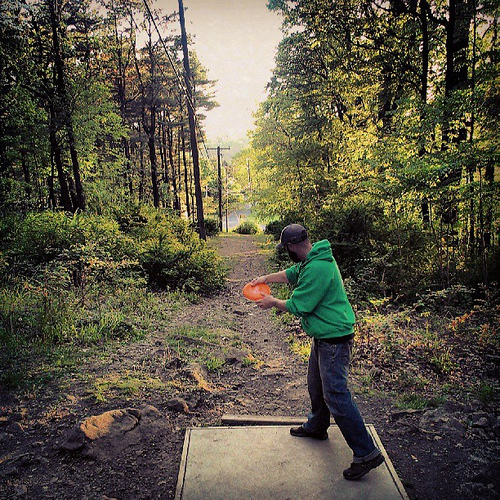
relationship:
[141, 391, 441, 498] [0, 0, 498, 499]
platform in woods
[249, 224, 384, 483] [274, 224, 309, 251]
man wears cap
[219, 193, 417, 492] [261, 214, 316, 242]
man wearing cap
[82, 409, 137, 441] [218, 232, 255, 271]
footprints in road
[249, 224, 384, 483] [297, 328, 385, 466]
man wearing blue jeans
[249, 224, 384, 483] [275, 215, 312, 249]
man wearing a cap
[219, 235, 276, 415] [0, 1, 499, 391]
path in forest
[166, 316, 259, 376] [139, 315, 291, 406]
green grass growing on dirt path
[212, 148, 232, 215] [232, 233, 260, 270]
pole beside path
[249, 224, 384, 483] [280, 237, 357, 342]
man wearing a green jacket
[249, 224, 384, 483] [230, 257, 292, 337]
man holding frisbee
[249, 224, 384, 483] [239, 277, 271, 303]
man throwing a frisbee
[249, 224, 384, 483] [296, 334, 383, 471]
man wearing blue jeans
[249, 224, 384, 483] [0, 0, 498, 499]
man standing in woods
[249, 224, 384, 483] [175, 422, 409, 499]
man standing on platform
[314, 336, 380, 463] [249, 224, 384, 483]
leg on man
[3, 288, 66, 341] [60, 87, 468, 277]
green vegetation in field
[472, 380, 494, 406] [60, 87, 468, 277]
green vegetation in field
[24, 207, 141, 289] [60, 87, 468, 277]
vegetation in field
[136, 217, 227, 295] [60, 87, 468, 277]
green vegetation in field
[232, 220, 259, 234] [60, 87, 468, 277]
green vegetation in field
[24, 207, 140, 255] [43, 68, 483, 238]
vegetation in field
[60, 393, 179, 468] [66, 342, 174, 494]
rock on ground